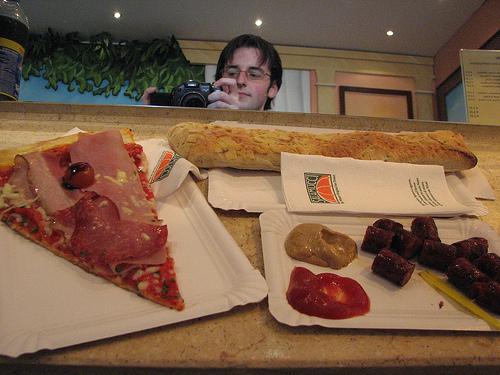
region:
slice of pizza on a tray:
[0, 127, 261, 367]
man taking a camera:
[139, 30, 289, 112]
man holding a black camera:
[125, 34, 295, 111]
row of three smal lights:
[112, 7, 411, 47]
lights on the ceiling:
[104, 1, 415, 60]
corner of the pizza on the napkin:
[64, 123, 209, 200]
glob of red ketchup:
[284, 258, 375, 329]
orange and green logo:
[297, 171, 344, 208]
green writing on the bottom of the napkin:
[405, 166, 454, 215]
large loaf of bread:
[157, 113, 472, 180]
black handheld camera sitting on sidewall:
[147, 79, 225, 108]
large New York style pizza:
[1, 121, 201, 317]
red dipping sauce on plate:
[275, 260, 377, 325]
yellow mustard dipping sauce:
[279, 214, 359, 272]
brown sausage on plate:
[355, 215, 498, 332]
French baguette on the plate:
[157, 117, 480, 172]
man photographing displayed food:
[125, 29, 290, 110]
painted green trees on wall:
[5, 14, 202, 105]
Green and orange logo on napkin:
[302, 165, 343, 207]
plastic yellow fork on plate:
[417, 266, 499, 339]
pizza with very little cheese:
[0, 120, 185, 321]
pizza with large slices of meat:
[0, 120, 186, 327]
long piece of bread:
[164, 103, 479, 178]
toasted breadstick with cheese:
[162, 111, 483, 178]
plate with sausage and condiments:
[265, 194, 497, 339]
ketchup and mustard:
[280, 219, 377, 326]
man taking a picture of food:
[131, 36, 292, 116]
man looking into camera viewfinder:
[124, 23, 296, 121]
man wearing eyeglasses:
[127, 25, 291, 129]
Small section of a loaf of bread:
[171, 115, 238, 171]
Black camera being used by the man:
[150, 78, 210, 111]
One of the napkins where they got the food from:
[279, 151, 447, 211]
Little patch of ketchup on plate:
[293, 277, 308, 299]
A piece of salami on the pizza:
[78, 203, 158, 255]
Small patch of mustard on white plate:
[288, 230, 318, 257]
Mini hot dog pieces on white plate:
[364, 217, 419, 288]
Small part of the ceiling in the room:
[311, 5, 324, 26]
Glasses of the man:
[221, 63, 267, 83]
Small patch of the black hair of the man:
[235, 36, 257, 46]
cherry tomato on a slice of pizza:
[60, 158, 98, 184]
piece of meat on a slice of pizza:
[55, 190, 167, 255]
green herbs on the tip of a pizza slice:
[156, 280, 177, 300]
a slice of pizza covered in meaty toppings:
[1, 125, 189, 311]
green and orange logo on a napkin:
[146, 146, 181, 185]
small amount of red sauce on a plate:
[282, 259, 371, 321]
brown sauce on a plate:
[282, 219, 359, 270]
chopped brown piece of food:
[370, 248, 418, 288]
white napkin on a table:
[278, 153, 445, 215]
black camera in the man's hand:
[145, 79, 226, 107]